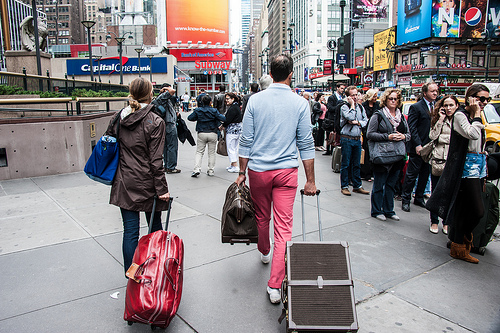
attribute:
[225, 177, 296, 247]
bag — large, leather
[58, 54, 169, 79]
sign — blue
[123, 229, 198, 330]
luggage — red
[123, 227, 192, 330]
suitcase — red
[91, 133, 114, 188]
bag — small, blue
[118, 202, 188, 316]
suit case — red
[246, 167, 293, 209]
pants — pink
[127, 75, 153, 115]
hair — blonde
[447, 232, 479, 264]
boots — brown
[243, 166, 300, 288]
pants — pink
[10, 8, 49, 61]
statue — large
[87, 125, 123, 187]
bag — blue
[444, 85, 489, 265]
woman/brown boots — brown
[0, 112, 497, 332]
street — busy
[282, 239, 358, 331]
suitecase — brown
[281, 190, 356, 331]
suitcase — brown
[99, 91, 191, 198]
coat — brown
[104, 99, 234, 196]
jacket — brown